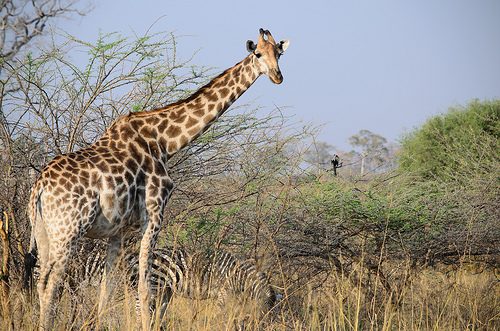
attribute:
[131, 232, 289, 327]
zebra — grazing, hiding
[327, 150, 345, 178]
bird — black, small, perched, sitting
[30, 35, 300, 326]
giraffe — tall, standing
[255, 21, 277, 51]
horns — tan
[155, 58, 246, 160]
neck — long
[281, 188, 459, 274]
limbs — tangled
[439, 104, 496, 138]
leaves — green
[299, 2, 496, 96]
sky — blue, clear, above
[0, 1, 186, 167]
limbs — tall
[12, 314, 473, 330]
grass — tall, dry, yellow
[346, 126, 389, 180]
tree — green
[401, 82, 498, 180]
bush — green